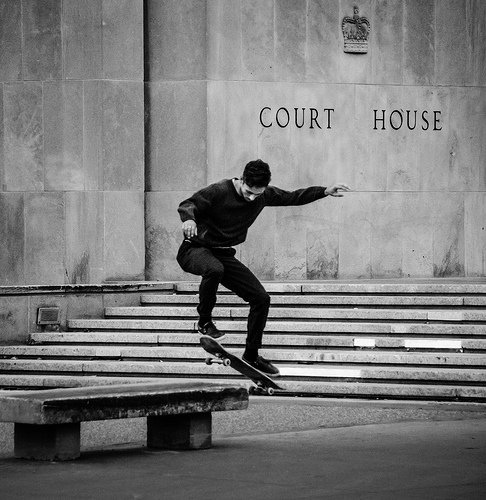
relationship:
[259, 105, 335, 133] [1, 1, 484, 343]
word on building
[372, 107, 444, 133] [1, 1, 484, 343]
word on building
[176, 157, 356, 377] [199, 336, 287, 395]
man tricking on skateboard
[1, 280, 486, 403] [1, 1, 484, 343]
steps leading to building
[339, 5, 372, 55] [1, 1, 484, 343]
crown on building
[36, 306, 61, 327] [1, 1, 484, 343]
vent on building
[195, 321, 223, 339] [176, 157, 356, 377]
sneaker on man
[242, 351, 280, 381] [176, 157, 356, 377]
sneaker on man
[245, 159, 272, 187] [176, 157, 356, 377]
hair of man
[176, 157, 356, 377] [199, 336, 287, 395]
man using skateboard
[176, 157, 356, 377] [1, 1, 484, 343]
man in front of building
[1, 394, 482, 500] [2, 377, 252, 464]
ground below bench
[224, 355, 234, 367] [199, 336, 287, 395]
wheel of skateboard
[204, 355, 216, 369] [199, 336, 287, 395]
wheel of skateboard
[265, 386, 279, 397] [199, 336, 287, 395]
wheel of skateboard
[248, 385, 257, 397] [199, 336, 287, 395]
wheel of skateboard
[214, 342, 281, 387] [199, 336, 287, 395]
edge of skateboard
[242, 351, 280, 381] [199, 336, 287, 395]
shoe on skateboard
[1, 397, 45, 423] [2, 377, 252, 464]
edge of bench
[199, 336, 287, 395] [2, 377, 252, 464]
skateboard over bench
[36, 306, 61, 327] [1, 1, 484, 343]
vent hanging on building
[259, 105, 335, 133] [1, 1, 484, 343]
word carved onto building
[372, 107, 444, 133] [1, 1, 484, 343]
word carved onto building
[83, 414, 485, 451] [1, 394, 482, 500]
seam in ground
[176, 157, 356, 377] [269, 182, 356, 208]
man holding out h arm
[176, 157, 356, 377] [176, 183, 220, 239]
man holding out h arm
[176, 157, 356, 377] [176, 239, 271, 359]
man wearing pants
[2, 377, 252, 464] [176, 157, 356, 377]
bench near man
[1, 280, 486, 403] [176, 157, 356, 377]
steps near man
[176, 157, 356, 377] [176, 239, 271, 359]
man wearing a pair of pants